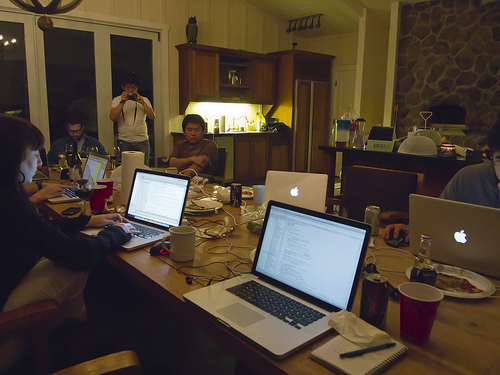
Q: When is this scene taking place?
A: Night time.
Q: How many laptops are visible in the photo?
A: Five.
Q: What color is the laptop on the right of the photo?
A: Silver.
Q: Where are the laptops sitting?
A: Table.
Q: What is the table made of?
A: Wood.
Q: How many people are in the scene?
A: Five.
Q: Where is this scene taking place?
A: In a conference room.